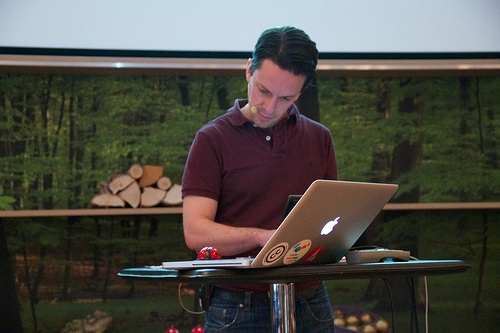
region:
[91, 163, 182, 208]
a pile of fire wood behind the man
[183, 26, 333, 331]
man standing at a podium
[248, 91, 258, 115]
the man's microphone by his mouth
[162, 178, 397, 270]
an apple laptop computer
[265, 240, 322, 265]
three stickers on the laptop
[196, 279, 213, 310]
cellphone on the man's belt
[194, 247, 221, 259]
lady bug timer on the computer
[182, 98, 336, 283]
maroon polo style shirt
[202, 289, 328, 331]
dark blue jeans with a black belt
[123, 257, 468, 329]
presentation podium with a laptop on it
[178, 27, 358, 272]
the man using the laptop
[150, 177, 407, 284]
the laptop is on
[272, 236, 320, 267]
stickers on the laptop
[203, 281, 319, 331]
man wearing blue jeans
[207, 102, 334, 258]
the man wearing a burgundy polo shirt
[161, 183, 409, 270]
the laptop on the table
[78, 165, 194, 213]
a stack of wood behind the man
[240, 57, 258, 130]
man wearing a microphone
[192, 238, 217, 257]
the ladybug mouse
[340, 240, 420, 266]
remote beside the laptop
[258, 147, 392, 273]
Grey macbook pro laptop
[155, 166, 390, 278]
Man has a macbook pro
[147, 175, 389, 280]
The laptop is powered on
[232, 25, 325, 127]
Man is looking down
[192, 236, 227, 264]
Lady bug on computer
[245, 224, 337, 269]
Stickers on back of computer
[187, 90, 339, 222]
Man is wearing red polo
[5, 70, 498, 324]
Forest scenery in background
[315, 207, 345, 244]
Apple logo on laptop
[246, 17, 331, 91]
Man has black hair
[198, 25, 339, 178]
this is a man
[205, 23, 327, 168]
the man is using a laptop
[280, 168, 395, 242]
this is a laptop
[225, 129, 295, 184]
this is the t shirt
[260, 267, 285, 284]
this is a table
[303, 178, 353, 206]
the laptop is grey in color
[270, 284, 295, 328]
this is the leg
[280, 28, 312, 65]
this is the hair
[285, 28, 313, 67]
the hair is black in color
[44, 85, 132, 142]
this is the leaf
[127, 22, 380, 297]
a man standing at a table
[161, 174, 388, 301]
a laptop on a table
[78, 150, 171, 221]
pieces of fire wood on a shelf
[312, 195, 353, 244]
a logo on a laptop computer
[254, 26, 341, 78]
a man with dark hair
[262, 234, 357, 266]
a laptop with stickers on it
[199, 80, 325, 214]
a man wearing a maroon shirt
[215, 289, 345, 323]
a man wearing blue jeans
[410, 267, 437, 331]
a cord hanging from a table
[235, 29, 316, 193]
a man looking down